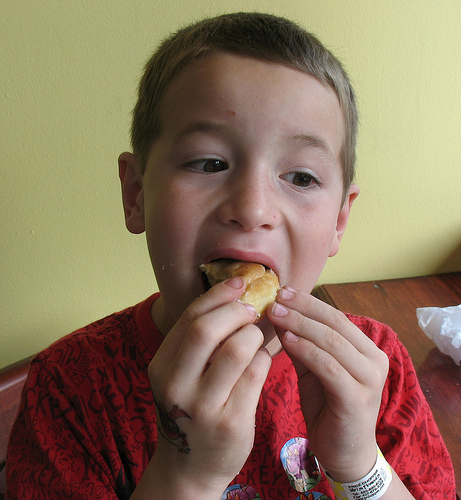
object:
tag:
[309, 449, 397, 499]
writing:
[347, 478, 387, 499]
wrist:
[318, 445, 396, 500]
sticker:
[279, 438, 321, 493]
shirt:
[18, 290, 438, 498]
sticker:
[221, 483, 261, 499]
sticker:
[291, 491, 331, 499]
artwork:
[148, 383, 193, 458]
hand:
[148, 275, 273, 487]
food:
[197, 258, 281, 320]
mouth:
[196, 246, 284, 308]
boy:
[20, 11, 437, 499]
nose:
[215, 167, 284, 231]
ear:
[116, 151, 145, 234]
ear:
[329, 184, 362, 259]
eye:
[183, 151, 229, 178]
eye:
[278, 165, 319, 191]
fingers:
[267, 285, 374, 393]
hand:
[264, 286, 391, 469]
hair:
[127, 12, 359, 172]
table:
[310, 270, 460, 499]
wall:
[0, 0, 460, 273]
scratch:
[227, 108, 237, 115]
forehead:
[165, 59, 347, 138]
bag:
[414, 303, 461, 365]